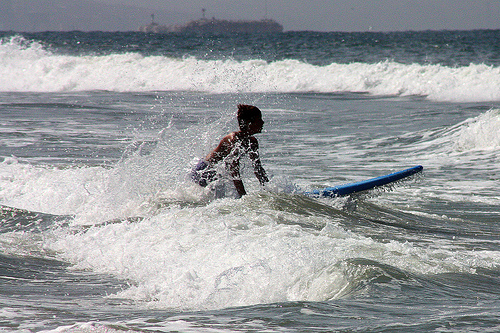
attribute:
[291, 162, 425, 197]
surfboard — wet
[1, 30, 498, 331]
water — tumultous, zealous, boisterous, splashing, white, blue, green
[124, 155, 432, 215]
surfboard — blue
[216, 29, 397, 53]
water — choppy, blue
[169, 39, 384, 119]
water — green, blue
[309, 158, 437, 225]
surfboard — blue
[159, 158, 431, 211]
surfboard — blue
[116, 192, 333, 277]
wave — rolling , low 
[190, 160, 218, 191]
suit — purple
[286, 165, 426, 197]
surfboard — blue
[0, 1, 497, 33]
sky — clear, blue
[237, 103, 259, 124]
hair — dark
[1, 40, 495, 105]
waves — white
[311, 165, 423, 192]
surfboard — blue 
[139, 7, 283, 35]
freighter — large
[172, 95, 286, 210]
boy — wet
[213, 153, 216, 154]
skin — tanned 